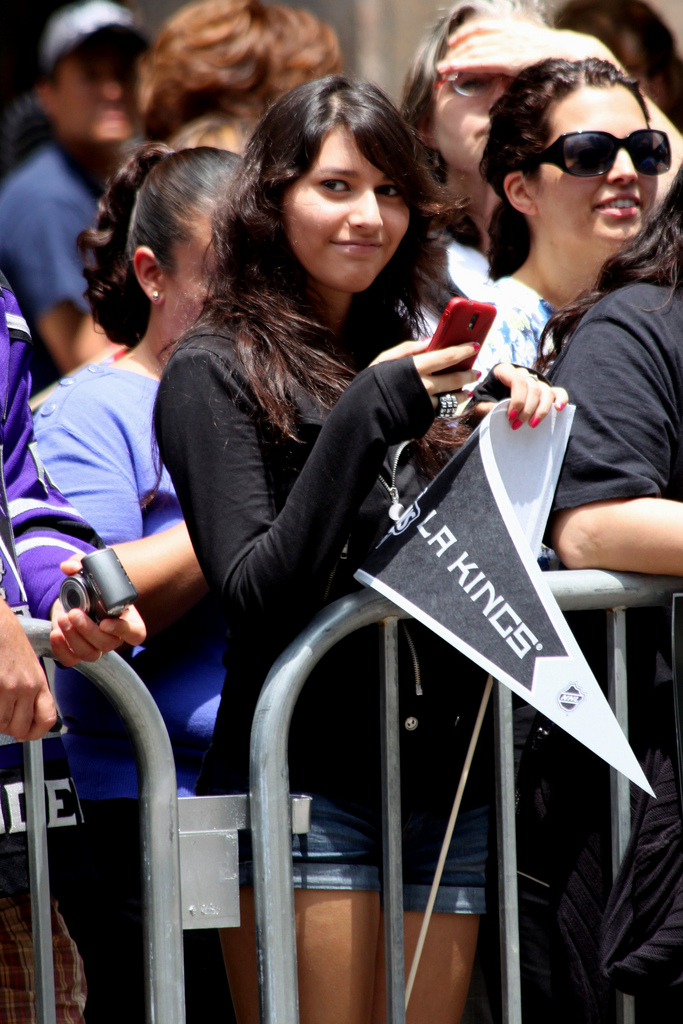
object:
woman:
[156, 69, 572, 1024]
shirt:
[150, 287, 525, 818]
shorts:
[242, 751, 524, 924]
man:
[0, 2, 158, 382]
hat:
[42, 2, 159, 71]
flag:
[353, 397, 658, 800]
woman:
[469, 54, 676, 386]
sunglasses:
[515, 128, 673, 182]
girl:
[153, 72, 573, 1024]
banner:
[349, 373, 658, 808]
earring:
[152, 290, 161, 301]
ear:
[133, 246, 165, 306]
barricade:
[247, 566, 683, 1024]